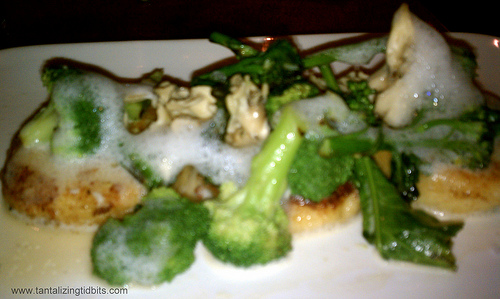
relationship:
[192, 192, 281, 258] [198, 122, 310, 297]
head of broccoli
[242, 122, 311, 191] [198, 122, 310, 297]
stem of broccoli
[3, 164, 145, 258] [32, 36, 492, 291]
chicken on plate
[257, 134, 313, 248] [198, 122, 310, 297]
piece of broccoli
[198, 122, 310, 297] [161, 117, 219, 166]
broccoli with soap